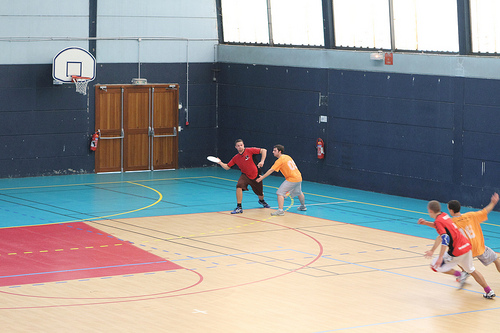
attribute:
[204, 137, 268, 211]
man — holding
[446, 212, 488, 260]
shirt — yellow, white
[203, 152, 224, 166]
frisbee — white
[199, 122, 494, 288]
boys — wearing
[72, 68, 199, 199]
door — large, brown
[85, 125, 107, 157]
fire extinguisher — red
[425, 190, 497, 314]
person basketball — playing